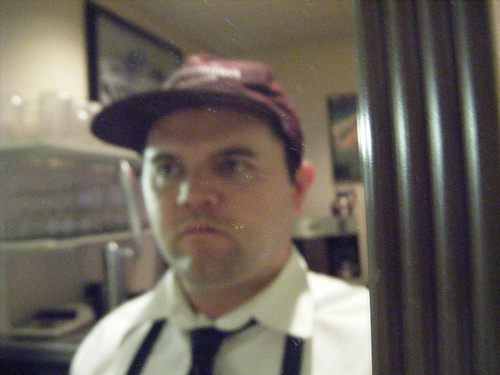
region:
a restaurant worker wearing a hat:
[26, 23, 433, 373]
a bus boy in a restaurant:
[31, 45, 434, 374]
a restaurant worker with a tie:
[38, 37, 406, 373]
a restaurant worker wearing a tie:
[33, 28, 414, 374]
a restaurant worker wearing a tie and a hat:
[55, 43, 461, 371]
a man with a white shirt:
[36, 43, 390, 374]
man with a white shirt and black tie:
[35, 30, 417, 374]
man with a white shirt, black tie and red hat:
[25, 35, 382, 373]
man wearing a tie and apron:
[40, 33, 435, 373]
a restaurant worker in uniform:
[54, 45, 384, 372]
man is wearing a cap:
[77, 35, 307, 177]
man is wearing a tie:
[151, 292, 246, 373]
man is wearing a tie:
[172, 305, 218, 374]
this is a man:
[79, 63, 322, 365]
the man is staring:
[112, 85, 321, 361]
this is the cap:
[84, 55, 276, 129]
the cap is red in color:
[88, 52, 271, 126]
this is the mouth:
[171, 216, 238, 253]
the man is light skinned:
[249, 194, 280, 236]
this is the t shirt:
[311, 284, 354, 324]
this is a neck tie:
[186, 332, 227, 368]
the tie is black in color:
[191, 325, 226, 374]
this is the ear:
[287, 160, 315, 215]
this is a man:
[95, 84, 370, 370]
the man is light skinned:
[251, 188, 281, 242]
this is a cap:
[191, 62, 261, 109]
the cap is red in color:
[206, 63, 275, 100]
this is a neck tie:
[189, 329, 211, 371]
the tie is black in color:
[183, 332, 220, 367]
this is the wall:
[12, 5, 74, 83]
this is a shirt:
[318, 289, 365, 357]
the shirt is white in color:
[326, 300, 349, 357]